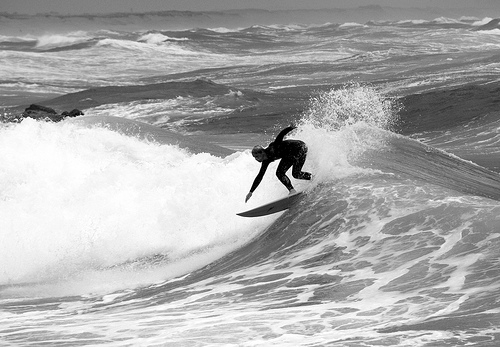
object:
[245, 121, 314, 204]
man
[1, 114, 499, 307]
wave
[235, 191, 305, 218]
surfboard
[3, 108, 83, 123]
rocks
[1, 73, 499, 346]
water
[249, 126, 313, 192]
wetsuit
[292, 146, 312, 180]
leg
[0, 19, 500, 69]
beach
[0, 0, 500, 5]
sky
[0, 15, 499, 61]
waves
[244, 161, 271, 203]
arm